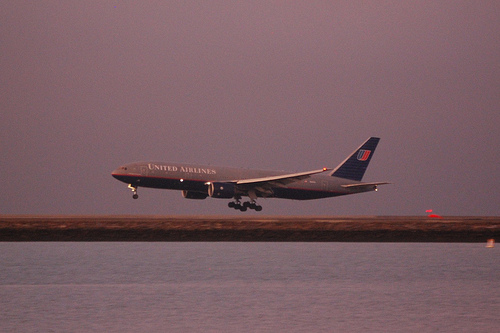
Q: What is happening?
A: An aircraft is landing.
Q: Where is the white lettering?
A: On the gray airplane.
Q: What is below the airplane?
A: The water.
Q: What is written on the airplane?
A: United Airlines.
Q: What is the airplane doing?
A: Flying through the air.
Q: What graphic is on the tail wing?
A: A blue and red logo.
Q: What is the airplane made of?
A: Metal.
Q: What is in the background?
A: The sky.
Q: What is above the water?
A: The airplane.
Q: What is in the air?
A: The airplane.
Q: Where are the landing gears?
A: Exposed on the bottom of the airplane.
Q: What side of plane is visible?
A: Left side.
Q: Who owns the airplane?
A: United Airlines.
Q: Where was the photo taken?
A: Runway.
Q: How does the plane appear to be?
A: Taking off.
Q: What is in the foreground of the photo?
A: Water.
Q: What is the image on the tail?
A: Flag.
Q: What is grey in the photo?
A: Airplane.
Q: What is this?
A: Plane.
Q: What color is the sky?
A: Gray.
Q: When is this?
A: Evening.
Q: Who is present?
A: Nobody.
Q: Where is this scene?
A: At the airport.